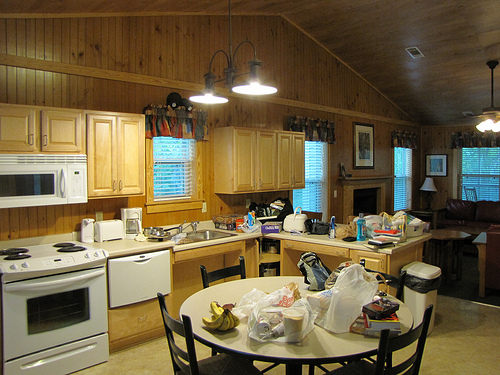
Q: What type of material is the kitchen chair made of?
A: Wood.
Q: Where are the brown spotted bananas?
A: On top of the table.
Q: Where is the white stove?
A: Beneath the microwave.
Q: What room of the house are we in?
A: Kitchen.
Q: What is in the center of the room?
A: Table.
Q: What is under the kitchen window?
A: Sink.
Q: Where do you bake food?
A: In the oven.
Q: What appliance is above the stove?
A: Microwave.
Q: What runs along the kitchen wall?
A: Cabinets.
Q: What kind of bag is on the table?
A: Plastic.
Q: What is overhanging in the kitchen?
A: Lights.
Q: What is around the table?
A: Chairs.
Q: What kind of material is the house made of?
A: Wood.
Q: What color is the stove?
A: White.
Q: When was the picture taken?
A: Daytime.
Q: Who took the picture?
A: Owner of home.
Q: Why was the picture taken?
A: To show the use of wood.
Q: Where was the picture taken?
A: From the kitchen.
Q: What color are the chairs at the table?
A: Black.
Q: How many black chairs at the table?
A: 4.